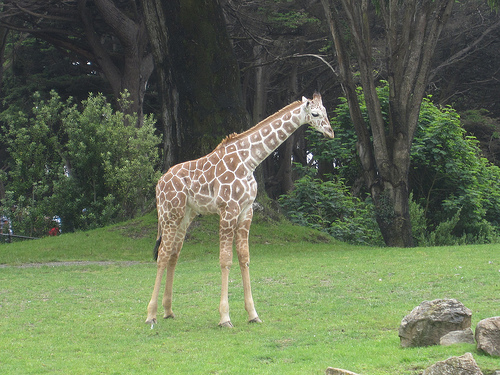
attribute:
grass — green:
[0, 202, 498, 374]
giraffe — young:
[145, 88, 334, 329]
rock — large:
[399, 297, 473, 350]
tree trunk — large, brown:
[349, 103, 418, 245]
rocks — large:
[401, 295, 498, 373]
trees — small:
[255, 0, 498, 245]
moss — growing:
[175, 3, 243, 218]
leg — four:
[238, 224, 265, 323]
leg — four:
[215, 210, 237, 331]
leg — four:
[142, 225, 168, 338]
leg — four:
[165, 247, 187, 319]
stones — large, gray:
[380, 290, 498, 373]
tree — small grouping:
[1, 1, 157, 122]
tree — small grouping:
[1, 82, 166, 245]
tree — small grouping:
[2, 3, 107, 102]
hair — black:
[148, 238, 161, 258]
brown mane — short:
[212, 129, 237, 146]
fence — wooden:
[0, 220, 40, 247]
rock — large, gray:
[395, 295, 474, 347]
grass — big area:
[26, 237, 492, 374]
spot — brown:
[256, 121, 275, 138]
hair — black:
[153, 240, 160, 258]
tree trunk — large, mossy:
[160, 2, 274, 219]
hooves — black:
[218, 320, 261, 327]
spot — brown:
[207, 160, 247, 193]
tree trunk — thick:
[143, 1, 254, 218]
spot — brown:
[169, 194, 183, 208]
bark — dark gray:
[366, 150, 421, 251]